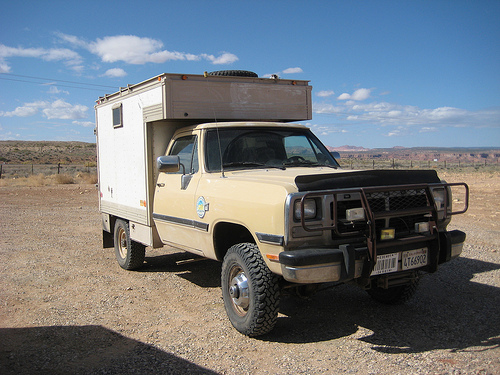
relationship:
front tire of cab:
[214, 237, 286, 339] [93, 70, 470, 337]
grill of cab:
[345, 178, 435, 224] [93, 70, 470, 337]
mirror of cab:
[157, 153, 181, 164] [93, 70, 470, 337]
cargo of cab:
[91, 70, 314, 278] [93, 70, 470, 337]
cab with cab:
[93, 70, 470, 337] [93, 70, 470, 337]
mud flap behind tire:
[97, 212, 117, 253] [110, 214, 148, 271]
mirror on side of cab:
[156, 155, 180, 172] [93, 70, 470, 337]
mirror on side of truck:
[156, 155, 180, 172] [152, 153, 191, 188]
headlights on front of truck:
[288, 171, 481, 228] [61, 79, 448, 349]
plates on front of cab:
[366, 250, 434, 275] [93, 70, 470, 337]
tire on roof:
[205, 68, 260, 78] [93, 73, 316, 123]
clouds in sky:
[331, 83, 499, 140] [2, 1, 488, 146]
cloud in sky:
[92, 32, 182, 65] [2, 1, 488, 146]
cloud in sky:
[0, 42, 46, 57] [2, 1, 488, 146]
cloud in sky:
[100, 67, 127, 77] [2, 1, 488, 146]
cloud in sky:
[282, 65, 301, 72] [2, 1, 488, 146]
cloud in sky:
[210, 51, 239, 65] [2, 1, 488, 146]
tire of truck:
[216, 239, 282, 340] [71, 63, 478, 291]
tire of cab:
[110, 214, 148, 271] [93, 70, 470, 337]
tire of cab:
[216, 239, 282, 344] [93, 70, 470, 337]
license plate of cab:
[401, 247, 428, 270] [93, 70, 470, 337]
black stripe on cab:
[152, 210, 211, 235] [93, 70, 470, 337]